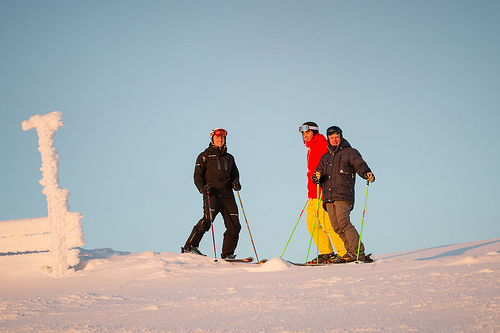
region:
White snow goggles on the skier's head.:
[296, 124, 317, 131]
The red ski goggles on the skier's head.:
[208, 127, 228, 135]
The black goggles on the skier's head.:
[325, 126, 342, 133]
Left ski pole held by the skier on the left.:
[202, 182, 222, 266]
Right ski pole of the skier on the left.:
[232, 182, 261, 264]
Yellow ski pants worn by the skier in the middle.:
[309, 195, 345, 257]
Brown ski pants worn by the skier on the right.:
[325, 203, 368, 258]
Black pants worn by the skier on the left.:
[197, 191, 242, 256]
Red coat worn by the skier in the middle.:
[300, 136, 331, 196]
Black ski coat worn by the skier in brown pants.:
[313, 144, 363, 197]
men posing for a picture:
[178, 88, 442, 294]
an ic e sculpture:
[20, 109, 103, 286]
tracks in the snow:
[126, 293, 181, 320]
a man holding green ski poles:
[317, 119, 375, 264]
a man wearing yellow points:
[298, 117, 333, 257]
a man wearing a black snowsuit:
[177, 114, 252, 283]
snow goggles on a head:
[300, 118, 322, 138]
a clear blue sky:
[3, 8, 470, 106]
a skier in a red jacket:
[286, 114, 333, 256]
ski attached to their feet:
[288, 254, 377, 268]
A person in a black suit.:
[182, 127, 262, 268]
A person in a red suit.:
[297, 124, 347, 262]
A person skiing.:
[314, 127, 374, 267]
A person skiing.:
[184, 130, 271, 267]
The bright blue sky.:
[0, 2, 498, 259]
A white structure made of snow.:
[0, 110, 80, 270]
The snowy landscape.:
[0, 251, 497, 328]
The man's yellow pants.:
[303, 195, 343, 256]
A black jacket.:
[310, 150, 367, 196]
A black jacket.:
[192, 150, 239, 197]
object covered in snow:
[0, 107, 104, 281]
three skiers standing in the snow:
[182, 95, 378, 273]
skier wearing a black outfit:
[173, 118, 260, 267]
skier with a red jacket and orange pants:
[291, 118, 329, 267]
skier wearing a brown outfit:
[313, 128, 388, 268]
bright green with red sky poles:
[281, 170, 373, 266]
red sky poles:
[202, 181, 267, 270]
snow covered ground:
[88, 247, 428, 331]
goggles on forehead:
[206, 121, 232, 147]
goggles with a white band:
[301, 119, 322, 137]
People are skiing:
[170, 107, 380, 272]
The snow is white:
[0, 220, 498, 330]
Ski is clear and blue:
[1, 0, 498, 254]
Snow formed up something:
[0, 107, 99, 286]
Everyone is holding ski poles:
[203, 167, 378, 268]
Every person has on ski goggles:
[188, 122, 360, 152]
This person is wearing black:
[178, 122, 265, 272]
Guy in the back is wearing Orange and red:
[282, 110, 378, 270]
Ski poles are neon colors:
[279, 168, 380, 265]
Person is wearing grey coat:
[309, 121, 384, 211]